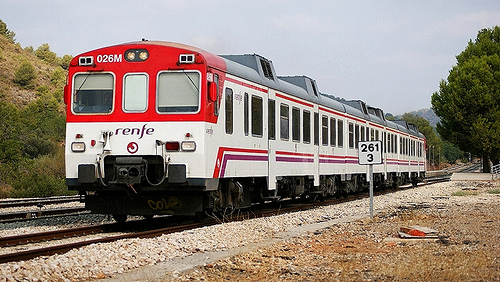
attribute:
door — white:
[268, 91, 275, 192]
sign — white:
[354, 136, 385, 166]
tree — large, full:
[441, 28, 497, 169]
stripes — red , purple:
[212, 148, 428, 173]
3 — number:
[364, 149, 378, 161]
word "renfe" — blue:
[110, 121, 157, 142]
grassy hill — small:
[0, 20, 84, 197]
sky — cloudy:
[3, 0, 498, 117]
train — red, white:
[28, 20, 497, 243]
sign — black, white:
[356, 137, 384, 167]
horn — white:
[96, 127, 118, 158]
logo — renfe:
[111, 114, 162, 140]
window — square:
[152, 68, 202, 117]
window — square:
[130, 80, 245, 118]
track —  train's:
[3, 215, 206, 266]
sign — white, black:
[357, 139, 383, 166]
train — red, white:
[67, 43, 433, 182]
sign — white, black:
[357, 139, 382, 216]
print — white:
[95, 52, 121, 62]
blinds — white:
[158, 72, 202, 109]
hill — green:
[0, 17, 83, 198]